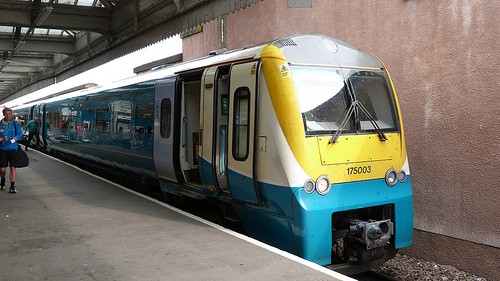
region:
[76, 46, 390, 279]
the train is yellow and blue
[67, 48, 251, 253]
the train is yellow and blue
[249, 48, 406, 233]
yellow blue and white passenger train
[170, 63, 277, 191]
yellow blue and white passenger train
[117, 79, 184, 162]
yellow blue and white passenger train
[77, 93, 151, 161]
yellow blue and white passenger train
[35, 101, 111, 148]
yellow blue and white passenger train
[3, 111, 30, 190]
woman standing at train platform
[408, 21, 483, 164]
red and white wall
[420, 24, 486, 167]
red and white wall in train station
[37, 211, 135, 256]
gray pavement in train station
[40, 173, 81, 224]
gray pavement in train station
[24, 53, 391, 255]
Blue, yellow, and white commuter train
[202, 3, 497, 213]
brown wall by tracks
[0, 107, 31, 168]
passenger in blue waiting by tracks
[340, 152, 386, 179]
train identification number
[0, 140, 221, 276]
concrete passenger platform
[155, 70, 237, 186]
ajar train car door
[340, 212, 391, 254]
connecter on front of train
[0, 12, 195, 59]
Metal overhang at railroad station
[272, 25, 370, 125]
light reflecting in train's windshield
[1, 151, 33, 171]
black skirt on person in blue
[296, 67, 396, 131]
window on front of train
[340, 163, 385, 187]
number on the train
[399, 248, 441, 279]
gravel next to the train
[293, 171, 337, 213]
light on the train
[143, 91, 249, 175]
door on the train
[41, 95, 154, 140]
windows on the train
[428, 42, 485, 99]
wall next to the train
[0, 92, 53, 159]
man on the sidewalk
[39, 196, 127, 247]
gray sidewalk next to train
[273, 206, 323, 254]
blue part of train